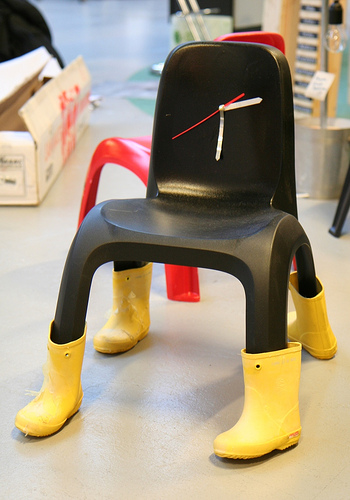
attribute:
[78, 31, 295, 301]
chair — red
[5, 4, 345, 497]
floor — white, painted, concrete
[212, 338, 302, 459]
boot — in the picture, yellow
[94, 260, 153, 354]
boot — yellow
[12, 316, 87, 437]
boot — yellow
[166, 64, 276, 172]
clock image — in the picture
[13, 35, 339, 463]
chair — black, plastic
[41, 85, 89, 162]
label — red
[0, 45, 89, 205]
box — white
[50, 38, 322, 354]
black chair — in the picture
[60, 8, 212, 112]
background — light blue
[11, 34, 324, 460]
black chair — in the picture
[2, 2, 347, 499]
room — in the picture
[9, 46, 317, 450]
chair boots — in the picture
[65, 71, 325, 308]
chair — red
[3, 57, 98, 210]
cardboard box — in the picture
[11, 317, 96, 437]
boot — yellow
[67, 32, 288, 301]
red chair — plastic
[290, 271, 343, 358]
rainboots — yellow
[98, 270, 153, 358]
rainboots — yellow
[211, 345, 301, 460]
rainboots — yellow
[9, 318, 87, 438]
rainboots — yellow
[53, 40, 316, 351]
chair — red, plastic, small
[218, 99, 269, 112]
hand — white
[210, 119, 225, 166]
hand — white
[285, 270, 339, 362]
boot — yellow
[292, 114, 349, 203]
bucket — in the picture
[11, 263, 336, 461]
boots — yellow